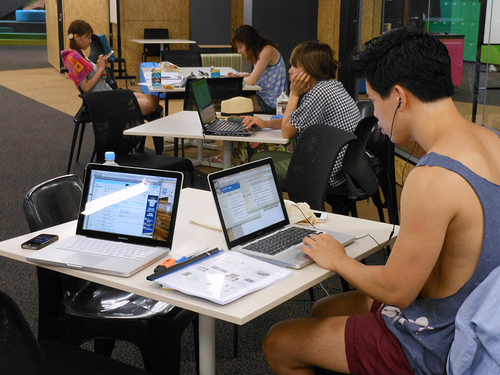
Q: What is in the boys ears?
A: Head phones.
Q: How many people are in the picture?
A: 4.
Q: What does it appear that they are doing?
A: Studying.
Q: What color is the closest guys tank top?
A: Blue.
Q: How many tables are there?
A: 4.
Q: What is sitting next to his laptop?
A: Papers.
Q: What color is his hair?
A: Black.